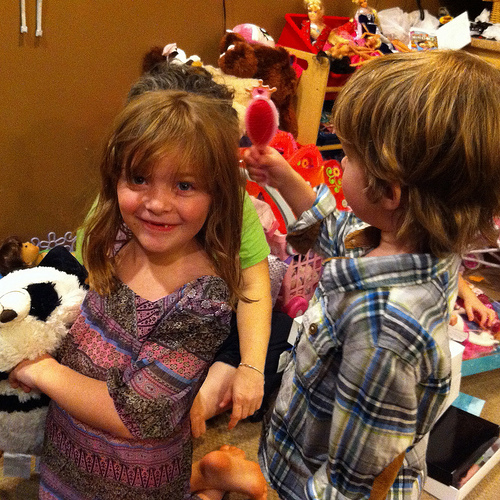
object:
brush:
[244, 93, 281, 163]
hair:
[333, 49, 500, 257]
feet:
[200, 447, 268, 499]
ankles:
[190, 449, 237, 495]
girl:
[5, 66, 247, 498]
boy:
[240, 48, 500, 499]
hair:
[78, 71, 262, 311]